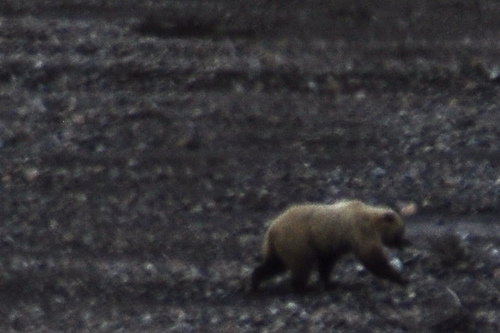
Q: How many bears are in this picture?
A: One.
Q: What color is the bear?
A: Brown.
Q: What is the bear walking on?
A: Dirt and rocks.